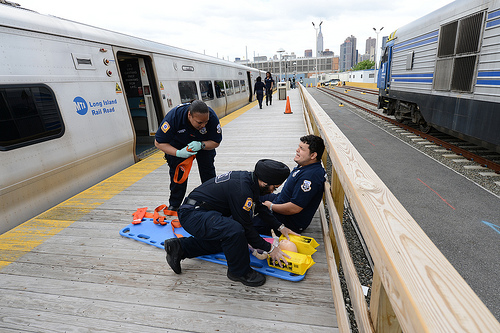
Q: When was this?
A: Daytime.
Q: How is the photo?
A: Clear.